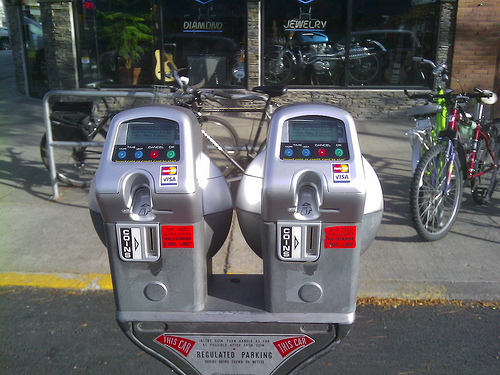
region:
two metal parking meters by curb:
[89, 100, 384, 374]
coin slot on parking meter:
[276, 220, 318, 260]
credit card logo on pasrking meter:
[327, 160, 362, 182]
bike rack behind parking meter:
[50, 85, 275, 208]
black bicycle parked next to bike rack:
[36, 62, 241, 187]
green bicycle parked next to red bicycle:
[402, 57, 499, 239]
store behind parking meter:
[50, 5, 499, 120]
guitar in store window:
[154, 28, 179, 85]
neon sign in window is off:
[281, 17, 331, 34]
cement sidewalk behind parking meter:
[7, 98, 499, 295]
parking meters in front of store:
[102, 93, 364, 353]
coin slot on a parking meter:
[112, 212, 167, 265]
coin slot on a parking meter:
[270, 214, 323, 268]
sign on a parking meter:
[156, 327, 323, 372]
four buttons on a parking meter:
[105, 139, 187, 160]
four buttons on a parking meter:
[272, 144, 347, 157]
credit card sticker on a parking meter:
[155, 161, 182, 196]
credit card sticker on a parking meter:
[327, 156, 354, 186]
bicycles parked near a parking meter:
[395, 56, 497, 240]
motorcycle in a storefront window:
[258, 13, 403, 83]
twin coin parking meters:
[88, 96, 386, 367]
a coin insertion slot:
[113, 226, 158, 264]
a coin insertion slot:
[278, 223, 320, 262]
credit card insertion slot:
[118, 181, 168, 218]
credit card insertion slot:
[286, 176, 337, 216]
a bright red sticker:
[158, 225, 193, 248]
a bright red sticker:
[321, 219, 360, 253]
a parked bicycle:
[401, 85, 497, 242]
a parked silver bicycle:
[152, 63, 279, 165]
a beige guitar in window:
[147, 20, 175, 88]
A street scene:
[6, 11, 498, 361]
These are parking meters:
[80, 98, 392, 366]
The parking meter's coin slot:
[276, 220, 323, 264]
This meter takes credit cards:
[156, 160, 185, 194]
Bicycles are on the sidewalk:
[394, 57, 497, 251]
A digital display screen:
[285, 117, 340, 144]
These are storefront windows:
[64, 0, 455, 99]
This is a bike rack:
[37, 81, 95, 198]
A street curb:
[4, 254, 111, 311]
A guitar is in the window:
[148, 17, 183, 89]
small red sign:
[152, 216, 200, 261]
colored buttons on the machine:
[274, 136, 363, 161]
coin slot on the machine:
[272, 216, 337, 274]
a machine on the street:
[69, 80, 400, 373]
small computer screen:
[272, 113, 351, 152]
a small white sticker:
[148, 157, 180, 189]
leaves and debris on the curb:
[363, 285, 469, 318]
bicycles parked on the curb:
[399, 38, 498, 253]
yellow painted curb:
[0, 258, 120, 305]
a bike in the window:
[244, 17, 413, 106]